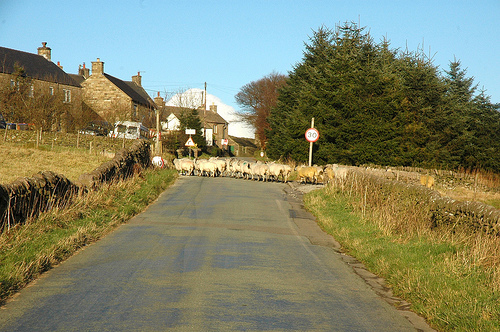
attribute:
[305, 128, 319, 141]
sign — circular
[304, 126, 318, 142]
sign — round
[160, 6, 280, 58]
clouds — white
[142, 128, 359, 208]
sheep — white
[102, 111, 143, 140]
bus — white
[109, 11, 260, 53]
clouds — white 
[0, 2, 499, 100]
sky — blue 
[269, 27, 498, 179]
trees — whitelarge, green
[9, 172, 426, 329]
road — small, country, black, paved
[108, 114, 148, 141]
van — large, grey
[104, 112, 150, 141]
van — white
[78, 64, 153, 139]
house — big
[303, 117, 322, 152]
sign — Red , white 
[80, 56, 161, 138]
brick building — brown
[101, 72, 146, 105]
roof — black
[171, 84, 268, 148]
clouds — white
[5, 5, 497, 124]
sky — blue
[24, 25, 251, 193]
building — Brown 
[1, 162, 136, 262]
fence — dirt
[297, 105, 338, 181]
pole — brown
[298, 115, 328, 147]
sign — white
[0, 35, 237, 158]
houses — big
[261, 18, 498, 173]
trees — tall, fat, green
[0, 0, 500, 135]
sky — blue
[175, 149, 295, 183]
sheeps — white, wooly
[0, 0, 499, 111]
sky — light blue, clear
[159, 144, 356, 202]
sheeps — white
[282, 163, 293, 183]
sheeps — white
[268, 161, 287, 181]
sheeps — white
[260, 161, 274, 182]
sheeps — white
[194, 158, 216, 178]
sheeps — white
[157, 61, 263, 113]
clouds — white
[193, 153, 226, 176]
sheep — white, wooly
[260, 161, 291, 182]
sheep — white, wooly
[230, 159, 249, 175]
sheep — white, wooly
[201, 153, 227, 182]
sheep — white, wooly